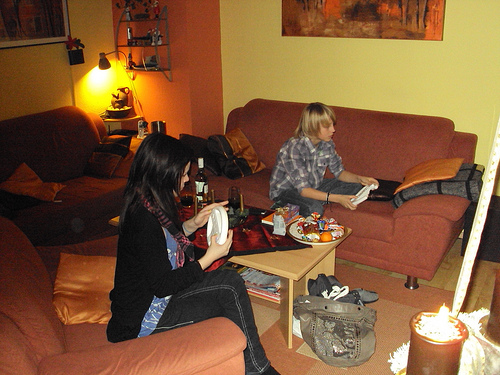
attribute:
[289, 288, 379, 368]
bag — gray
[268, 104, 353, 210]
boy — playing video game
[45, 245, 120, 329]
pillow — square, gold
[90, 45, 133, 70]
lamp — bent, a desk lamp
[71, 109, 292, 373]
lady — playing game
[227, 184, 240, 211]
glass — a drinking glass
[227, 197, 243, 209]
liquid — dark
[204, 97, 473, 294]
sofaset — red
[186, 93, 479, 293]
sofa — red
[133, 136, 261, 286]
girl — playing video game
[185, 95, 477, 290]
couch — brown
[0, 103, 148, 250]
couch — brown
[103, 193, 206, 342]
sweater — black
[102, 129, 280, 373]
lady — light skinned